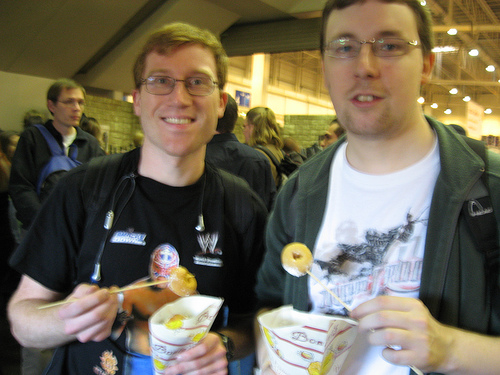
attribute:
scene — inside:
[34, 14, 496, 357]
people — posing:
[84, 30, 485, 315]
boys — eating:
[73, 10, 492, 343]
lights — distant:
[420, 14, 496, 125]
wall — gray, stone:
[85, 90, 163, 168]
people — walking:
[99, 82, 398, 193]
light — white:
[428, 13, 467, 59]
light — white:
[445, 46, 496, 106]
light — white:
[424, 62, 458, 105]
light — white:
[428, 30, 496, 70]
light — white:
[448, 87, 494, 119]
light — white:
[475, 95, 497, 123]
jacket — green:
[250, 113, 498, 372]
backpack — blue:
[36, 120, 92, 175]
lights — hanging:
[427, 12, 497, 136]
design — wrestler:
[316, 213, 416, 281]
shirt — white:
[311, 140, 443, 373]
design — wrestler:
[310, 211, 413, 278]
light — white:
[412, 88, 428, 111]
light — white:
[429, 93, 446, 125]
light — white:
[439, 102, 457, 114]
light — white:
[423, 7, 430, 9]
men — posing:
[3, 12, 483, 369]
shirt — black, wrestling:
[10, 137, 297, 370]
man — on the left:
[11, 13, 284, 365]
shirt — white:
[329, 136, 426, 372]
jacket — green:
[267, 111, 481, 347]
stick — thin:
[299, 263, 410, 373]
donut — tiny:
[273, 235, 321, 277]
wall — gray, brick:
[83, 98, 147, 153]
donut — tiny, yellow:
[160, 260, 205, 297]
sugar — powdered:
[162, 276, 179, 291]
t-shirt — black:
[7, 136, 267, 370]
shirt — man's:
[12, 140, 271, 368]